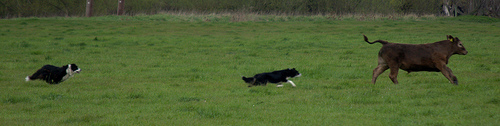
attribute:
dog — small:
[238, 62, 304, 91]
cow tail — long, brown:
[357, 30, 384, 47]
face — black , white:
[71, 62, 85, 73]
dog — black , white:
[20, 59, 83, 90]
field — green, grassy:
[18, 22, 470, 124]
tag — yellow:
[450, 36, 452, 43]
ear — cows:
[444, 33, 456, 40]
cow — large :
[358, 32, 470, 87]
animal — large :
[359, 32, 473, 93]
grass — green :
[136, 57, 169, 82]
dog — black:
[236, 51, 313, 100]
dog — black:
[15, 47, 92, 92]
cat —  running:
[223, 62, 330, 104]